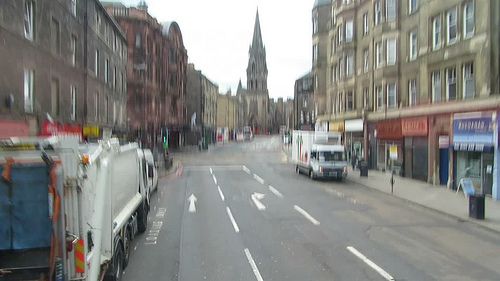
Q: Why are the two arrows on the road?
A: They show traffic direction.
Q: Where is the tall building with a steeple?
A: In the far background.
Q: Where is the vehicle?
A: It is on the street.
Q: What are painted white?
A: Broken lines in the street.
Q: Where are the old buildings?
A: They are on both sides of the street.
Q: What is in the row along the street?
A: A row of businesses.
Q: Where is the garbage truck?
A: On the left side of the street.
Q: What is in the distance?
A: Steeple.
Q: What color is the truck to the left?
A: White.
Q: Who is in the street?
A: Nobody.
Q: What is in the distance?
A: A tower.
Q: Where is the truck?
A: On the right.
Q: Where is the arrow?
A: On the road.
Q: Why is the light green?
A: To signal traffic.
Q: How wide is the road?
A: Three lanes.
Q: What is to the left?
A: A truck.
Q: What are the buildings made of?
A: Stone.